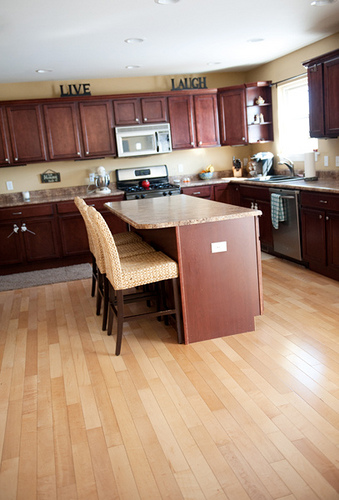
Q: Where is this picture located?
A: In a kitchen.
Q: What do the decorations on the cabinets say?
A: Live, laugh.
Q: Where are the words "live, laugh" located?
A: On top of the cabinets.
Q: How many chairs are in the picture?
A: Three.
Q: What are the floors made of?
A: Wood.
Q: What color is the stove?
A: Black.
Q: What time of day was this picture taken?
A: Midday.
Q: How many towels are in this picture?
A: One.